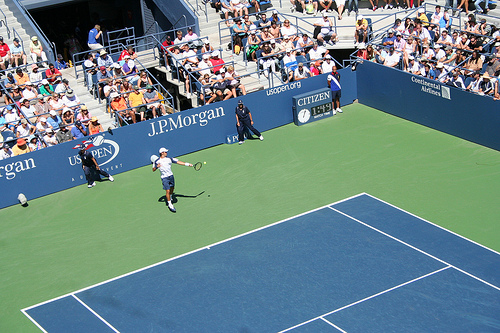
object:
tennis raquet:
[188, 160, 204, 172]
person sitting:
[293, 61, 314, 81]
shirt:
[150, 155, 180, 180]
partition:
[0, 55, 500, 214]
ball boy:
[234, 99, 266, 146]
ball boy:
[72, 144, 116, 189]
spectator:
[0, 0, 500, 167]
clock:
[289, 87, 335, 127]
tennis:
[0, 37, 500, 333]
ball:
[202, 161, 207, 165]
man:
[151, 146, 197, 214]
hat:
[158, 146, 170, 154]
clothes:
[234, 105, 263, 142]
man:
[326, 65, 345, 115]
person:
[312, 11, 338, 47]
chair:
[312, 24, 338, 47]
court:
[0, 97, 499, 331]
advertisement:
[146, 105, 228, 139]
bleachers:
[0, 0, 500, 162]